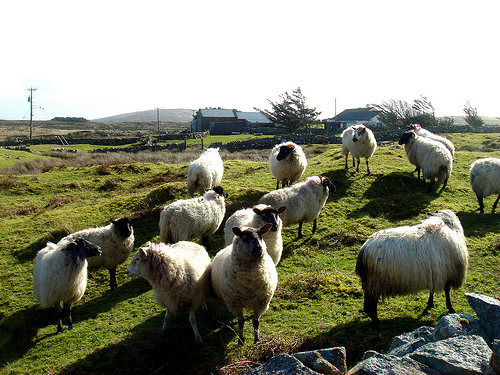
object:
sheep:
[210, 223, 278, 345]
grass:
[39, 330, 87, 361]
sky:
[0, 0, 497, 118]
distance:
[2, 99, 497, 153]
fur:
[170, 200, 215, 228]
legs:
[232, 301, 249, 345]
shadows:
[63, 307, 235, 375]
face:
[240, 230, 262, 257]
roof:
[326, 106, 381, 121]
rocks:
[293, 345, 348, 372]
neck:
[147, 253, 170, 287]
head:
[251, 204, 286, 233]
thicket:
[8, 146, 262, 176]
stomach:
[236, 285, 263, 308]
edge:
[418, 147, 452, 180]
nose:
[271, 222, 279, 228]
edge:
[332, 344, 347, 371]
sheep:
[354, 207, 469, 324]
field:
[2, 134, 500, 373]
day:
[12, 9, 467, 114]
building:
[193, 107, 241, 135]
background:
[0, 1, 500, 375]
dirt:
[3, 124, 23, 136]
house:
[324, 107, 390, 132]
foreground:
[0, 236, 500, 373]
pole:
[24, 86, 35, 140]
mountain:
[89, 108, 297, 124]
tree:
[252, 90, 322, 134]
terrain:
[1, 127, 298, 161]